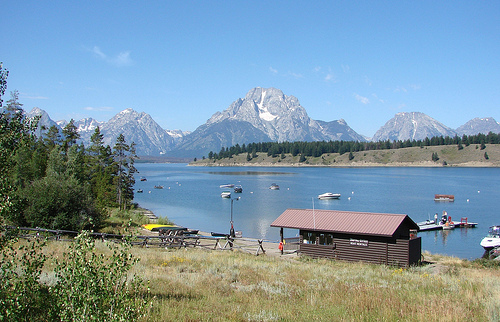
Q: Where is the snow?
A: On the mountains.